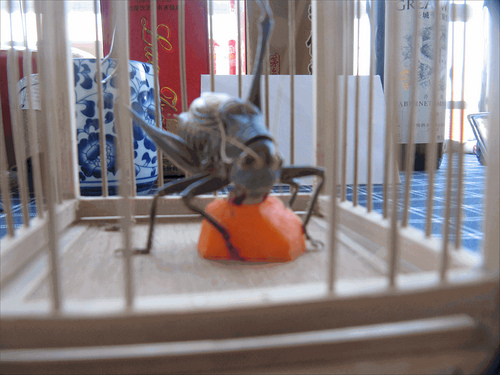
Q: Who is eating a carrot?
A: The bug.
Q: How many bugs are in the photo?
A: One.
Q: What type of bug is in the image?
A: A grasshopper.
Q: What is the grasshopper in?
A: A cage.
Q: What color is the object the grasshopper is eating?
A: Orange.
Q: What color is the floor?
A: Blue.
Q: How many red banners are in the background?
A: One.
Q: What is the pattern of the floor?
A: Tile.